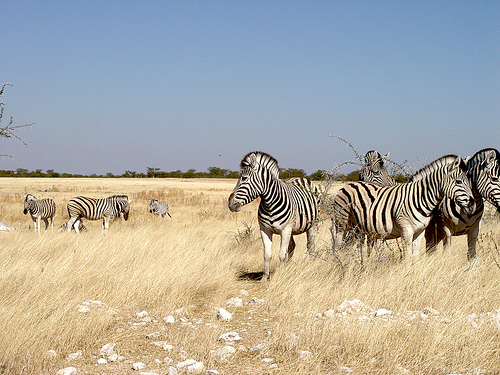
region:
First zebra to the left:
[20, 191, 55, 232]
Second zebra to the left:
[60, 190, 125, 225]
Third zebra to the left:
[145, 195, 170, 215]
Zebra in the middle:
[230, 150, 315, 280]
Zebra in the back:
[355, 150, 390, 190]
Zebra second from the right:
[330, 150, 470, 270]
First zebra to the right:
[420, 145, 495, 260]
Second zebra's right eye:
[451, 176, 466, 185]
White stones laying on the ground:
[35, 295, 490, 370]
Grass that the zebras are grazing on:
[1, 210, 246, 365]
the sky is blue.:
[3, 2, 485, 174]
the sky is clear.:
[1, 1, 498, 176]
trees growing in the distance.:
[0, 162, 371, 187]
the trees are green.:
[1, 159, 355, 184]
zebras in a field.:
[15, 137, 489, 281]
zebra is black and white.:
[221, 142, 322, 271]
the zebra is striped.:
[224, 143, 318, 263]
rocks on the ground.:
[47, 284, 402, 373]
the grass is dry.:
[3, 175, 498, 373]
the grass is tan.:
[2, 177, 494, 373]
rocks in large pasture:
[70, 300, 310, 373]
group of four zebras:
[225, 140, 496, 286]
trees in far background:
[0, 160, 357, 180]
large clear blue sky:
[1, 0, 497, 163]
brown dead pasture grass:
[0, 240, 196, 287]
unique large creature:
[224, 148, 325, 288]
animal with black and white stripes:
[65, 190, 131, 235]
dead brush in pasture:
[225, 217, 255, 257]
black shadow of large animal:
[235, 265, 270, 283]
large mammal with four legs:
[226, 146, 326, 287]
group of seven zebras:
[13, 121, 498, 291]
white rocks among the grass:
[36, 282, 498, 374]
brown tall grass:
[19, 227, 227, 295]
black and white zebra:
[221, 139, 331, 289]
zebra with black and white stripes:
[316, 155, 486, 277]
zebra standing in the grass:
[143, 191, 177, 239]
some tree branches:
[1, 108, 45, 167]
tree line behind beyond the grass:
[3, 165, 457, 190]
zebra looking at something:
[187, 141, 349, 303]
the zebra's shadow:
[223, 251, 282, 316]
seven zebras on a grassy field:
[9, 142, 499, 266]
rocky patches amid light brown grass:
[45, 282, 416, 366]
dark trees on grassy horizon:
[18, 162, 187, 184]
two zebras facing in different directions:
[18, 187, 136, 239]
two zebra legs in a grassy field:
[253, 226, 296, 281]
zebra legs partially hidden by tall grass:
[328, 233, 425, 273]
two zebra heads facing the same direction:
[411, 144, 498, 224]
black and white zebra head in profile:
[219, 148, 280, 213]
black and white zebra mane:
[238, 150, 283, 177]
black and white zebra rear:
[330, 178, 372, 247]